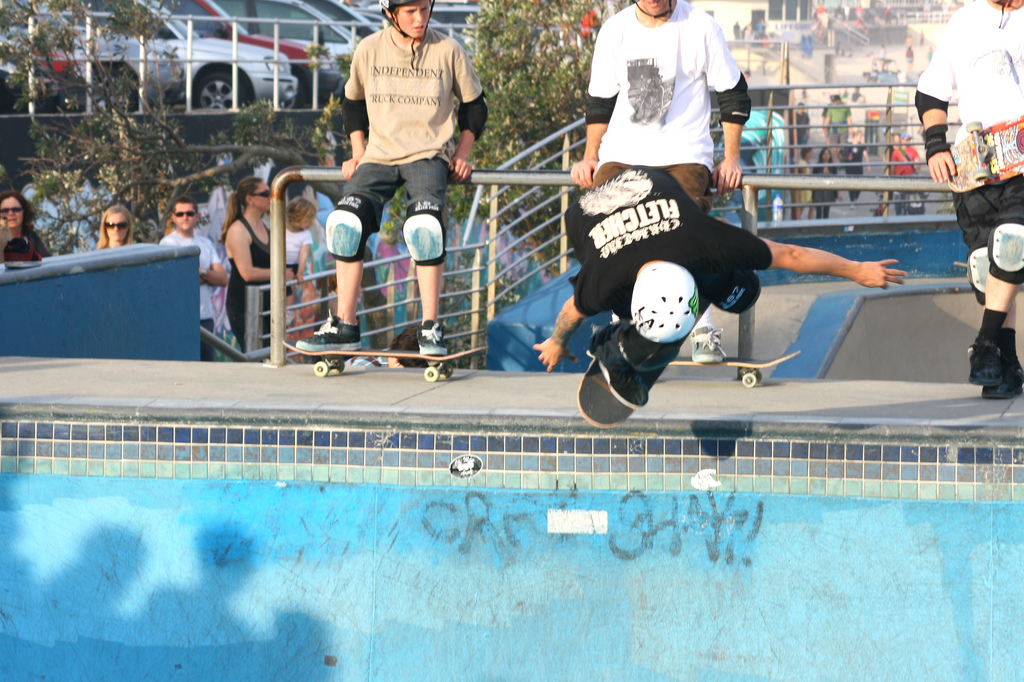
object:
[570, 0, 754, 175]
white shirt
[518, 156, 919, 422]
skateboarder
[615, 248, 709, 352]
helmet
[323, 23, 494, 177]
shirt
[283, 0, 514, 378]
boy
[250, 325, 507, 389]
skateboard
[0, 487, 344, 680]
reflection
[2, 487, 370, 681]
people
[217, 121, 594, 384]
gate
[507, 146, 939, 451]
trick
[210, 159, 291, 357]
woman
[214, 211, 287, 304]
tank top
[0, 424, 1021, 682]
ramp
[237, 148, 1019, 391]
railing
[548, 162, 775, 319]
shirt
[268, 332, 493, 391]
skateboards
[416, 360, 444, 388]
wheels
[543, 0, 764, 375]
skateboarder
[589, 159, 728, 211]
shorts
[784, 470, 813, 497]
brick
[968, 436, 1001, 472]
brick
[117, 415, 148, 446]
brick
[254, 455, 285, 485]
brick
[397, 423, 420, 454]
brick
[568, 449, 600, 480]
brick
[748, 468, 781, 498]
brick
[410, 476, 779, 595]
graffiti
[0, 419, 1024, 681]
pool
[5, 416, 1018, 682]
tiles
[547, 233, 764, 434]
skateboard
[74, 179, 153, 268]
woman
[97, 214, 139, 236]
sunglasses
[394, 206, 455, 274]
knee pad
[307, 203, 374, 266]
knee pad